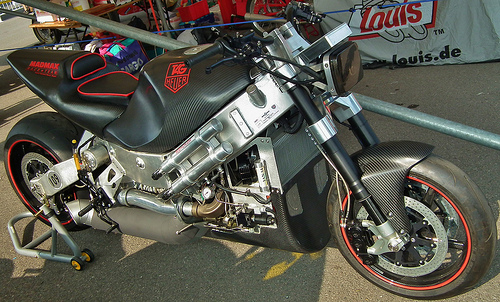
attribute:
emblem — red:
[163, 59, 192, 91]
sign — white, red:
[347, 2, 436, 34]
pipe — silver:
[43, 190, 244, 249]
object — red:
[388, 7, 452, 49]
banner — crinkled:
[311, 0, 498, 67]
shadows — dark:
[103, 240, 331, 299]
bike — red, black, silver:
[1, 1, 497, 299]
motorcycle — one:
[20, 19, 498, 286]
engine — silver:
[141, 81, 307, 238]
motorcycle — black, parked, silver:
[2, 15, 492, 298]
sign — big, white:
[348, 7, 465, 54]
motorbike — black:
[18, 30, 498, 275]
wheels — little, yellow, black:
[309, 142, 495, 297]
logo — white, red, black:
[344, 1, 437, 40]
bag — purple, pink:
[97, 37, 151, 75]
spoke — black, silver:
[285, 77, 397, 240]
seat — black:
[66, 54, 131, 95]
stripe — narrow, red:
[338, 172, 472, 291]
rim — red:
[352, 199, 449, 271]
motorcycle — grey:
[41, 73, 436, 258]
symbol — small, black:
[429, 27, 445, 35]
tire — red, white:
[352, 167, 487, 267]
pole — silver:
[13, 0, 499, 145]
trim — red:
[68, 51, 137, 97]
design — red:
[158, 57, 194, 98]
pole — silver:
[11, 1, 484, 171]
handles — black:
[182, 11, 331, 72]